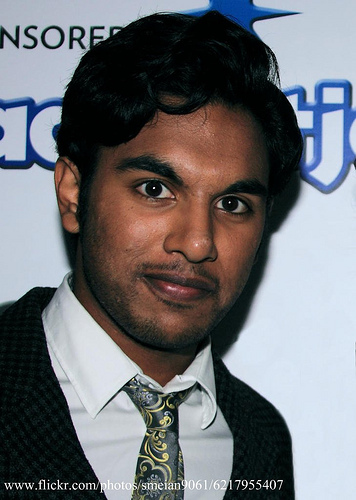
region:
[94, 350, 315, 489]
yellow and grey tie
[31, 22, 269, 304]
man with black hair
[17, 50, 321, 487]
man in dress suit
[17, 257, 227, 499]
man with white dress shirt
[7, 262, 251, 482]
man with dress jacket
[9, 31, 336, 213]
advertisement behind man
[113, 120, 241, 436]
man not smiling for picture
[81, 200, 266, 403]
man has a gotee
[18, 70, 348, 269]
blue lettering on advertisement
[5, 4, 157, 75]
black lettering on advertisement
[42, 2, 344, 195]
Man has short dark hair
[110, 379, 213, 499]
Man is wearing a tie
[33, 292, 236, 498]
Man is wearing a white dress shirt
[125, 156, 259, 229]
Man has brown colored eyes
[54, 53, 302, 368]
Man is looking at the camera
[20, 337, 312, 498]
Man is wearing a dark colored jacket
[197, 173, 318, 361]
Man is casting a shadow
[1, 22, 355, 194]
A white advertising billboard is behind him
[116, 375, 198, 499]
The man's tie has a yellow design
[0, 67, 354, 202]
Words behind the man is highlighted in blue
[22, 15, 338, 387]
face of an Indian man with large eyes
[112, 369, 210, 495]
black and gold paisley tie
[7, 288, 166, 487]
hounds tooth jacket with white shirt and paisley tie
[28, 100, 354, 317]
face of a man who has whiskers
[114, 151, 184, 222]
a brown eye with a bushy black eyebrow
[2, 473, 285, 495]
a website written in white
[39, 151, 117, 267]
a man's ear with side burns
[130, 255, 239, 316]
lips with facial hair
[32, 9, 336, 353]
Indian man with dark black hair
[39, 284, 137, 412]
white collared dress shirt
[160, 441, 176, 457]
section of a tie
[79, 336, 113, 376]
part of a white colar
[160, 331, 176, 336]
chin of a man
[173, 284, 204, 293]
lips of a man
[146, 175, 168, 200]
right eye of a man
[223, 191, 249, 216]
left eye of a man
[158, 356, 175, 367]
part of a man's neck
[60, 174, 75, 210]
right ear of a man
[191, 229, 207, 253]
nose of a man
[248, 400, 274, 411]
shoulder of a man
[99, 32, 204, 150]
Man has dark hair.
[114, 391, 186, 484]
Man is wearing tie.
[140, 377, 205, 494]
Tie is silver gray and yellow.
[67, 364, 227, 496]
Man is wearing white shirt.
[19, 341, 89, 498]
Man has on dark sport coat.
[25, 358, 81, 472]
Sport coat is dark and checkered.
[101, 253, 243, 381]
Man has a five o'clock shadow.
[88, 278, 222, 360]
Man has dark facial hair.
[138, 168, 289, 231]
Man has dark eyes.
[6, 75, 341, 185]
Blue outlining the writing in the background.